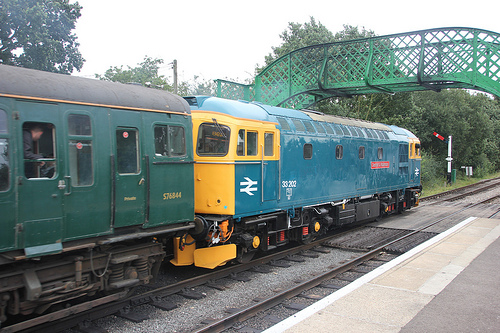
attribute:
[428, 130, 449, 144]
sign — white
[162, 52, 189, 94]
utility pole —  wooden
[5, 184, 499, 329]
track — Railroad 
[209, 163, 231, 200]
paint — yellow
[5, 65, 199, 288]
car — green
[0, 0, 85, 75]
leaves — green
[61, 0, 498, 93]
bright sky — cloudless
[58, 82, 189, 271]
train — green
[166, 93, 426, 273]
train car — under, blue, yellow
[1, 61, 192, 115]
roof — black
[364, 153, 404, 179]
lettering label — grey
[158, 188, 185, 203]
writting — yellow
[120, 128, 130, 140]
sticker — red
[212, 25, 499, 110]
bridge — green